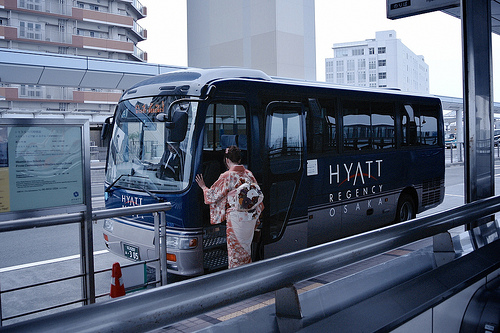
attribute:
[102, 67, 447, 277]
bus — parked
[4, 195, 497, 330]
guard rail — metal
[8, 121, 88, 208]
signs — informational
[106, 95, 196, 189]
windshield — large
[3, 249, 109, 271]
line — white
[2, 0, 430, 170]
buildings — several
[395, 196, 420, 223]
wheel — rear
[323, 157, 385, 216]
writing — white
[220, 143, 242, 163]
hair — black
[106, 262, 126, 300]
cone — orange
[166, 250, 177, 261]
light — orange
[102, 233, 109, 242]
light — orange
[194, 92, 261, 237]
bus door — opened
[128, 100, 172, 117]
digital sign — on bus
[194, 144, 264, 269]
woman — boarding a bus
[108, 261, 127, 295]
traffic cone — orange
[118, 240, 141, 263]
license plate — on front of bus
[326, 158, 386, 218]
hotel logo — on front of bus, on side of bus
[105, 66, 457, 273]
van — blue and grey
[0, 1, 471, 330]
dividing wall — metal and glass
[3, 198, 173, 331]
metal handrail — on top of wall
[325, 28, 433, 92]
multi-storied building — white